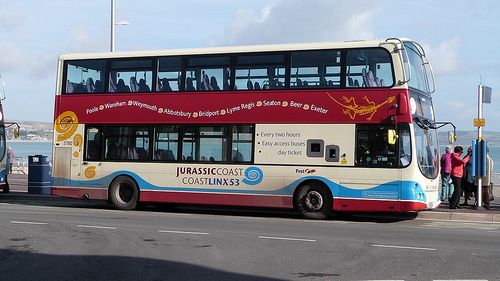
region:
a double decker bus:
[26, 33, 446, 245]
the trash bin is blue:
[23, 147, 60, 209]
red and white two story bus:
[50, 37, 442, 222]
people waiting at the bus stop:
[437, 142, 494, 208]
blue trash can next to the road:
[23, 153, 53, 196]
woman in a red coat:
[449, 145, 469, 207]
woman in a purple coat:
[437, 145, 454, 202]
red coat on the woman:
[450, 150, 470, 179]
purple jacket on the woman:
[440, 153, 455, 172]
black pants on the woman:
[447, 173, 464, 210]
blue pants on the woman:
[437, 175, 455, 200]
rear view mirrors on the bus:
[386, 119, 458, 152]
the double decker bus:
[48, 37, 455, 217]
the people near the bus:
[441, 142, 493, 208]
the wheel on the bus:
[293, 180, 332, 218]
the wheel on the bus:
[106, 174, 138, 209]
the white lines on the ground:
[10, 219, 436, 252]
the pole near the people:
[470, 84, 492, 208]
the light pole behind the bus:
[109, 0, 129, 50]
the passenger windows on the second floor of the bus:
[62, 45, 394, 90]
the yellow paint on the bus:
[54, 89, 395, 178]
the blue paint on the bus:
[51, 165, 441, 203]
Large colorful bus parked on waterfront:
[51, 35, 457, 219]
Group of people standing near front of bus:
[440, 143, 495, 211]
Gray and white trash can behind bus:
[26, 153, 51, 196]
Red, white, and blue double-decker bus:
[49, 36, 459, 219]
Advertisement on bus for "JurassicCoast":
[174, 164, 264, 186]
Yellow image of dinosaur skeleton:
[323, 90, 398, 122]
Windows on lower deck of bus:
[83, 120, 256, 167]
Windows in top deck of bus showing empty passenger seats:
[62, 45, 397, 95]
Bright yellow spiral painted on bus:
[53, 108, 77, 142]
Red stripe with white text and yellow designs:
[53, 85, 414, 124]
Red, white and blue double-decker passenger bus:
[51, 37, 442, 220]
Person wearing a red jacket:
[451, 145, 472, 209]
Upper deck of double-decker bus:
[56, 37, 441, 97]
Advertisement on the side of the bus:
[171, 162, 263, 190]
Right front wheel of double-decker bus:
[292, 179, 334, 221]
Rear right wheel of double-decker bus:
[107, 174, 141, 209]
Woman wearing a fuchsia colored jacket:
[438, 151, 449, 171]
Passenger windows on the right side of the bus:
[80, 120, 255, 165]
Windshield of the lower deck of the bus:
[410, 115, 435, 176]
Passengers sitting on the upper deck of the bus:
[67, 63, 363, 93]